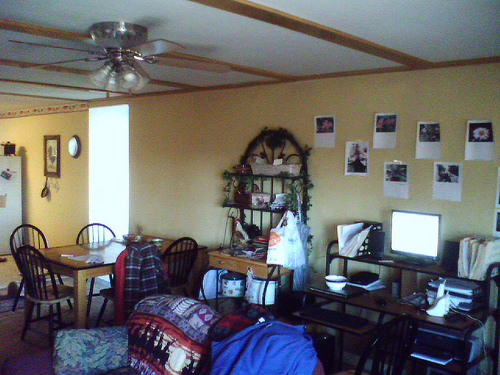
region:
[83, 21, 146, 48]
a shiny finished ceiling fan cover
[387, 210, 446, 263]
a flat screen computer monitor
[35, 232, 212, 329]
a light wood finished table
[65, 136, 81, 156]
clock with black rim hanging on wall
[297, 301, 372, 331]
a black keyboard on pull out shelf of desk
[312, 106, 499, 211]
papers hanging above computer on wall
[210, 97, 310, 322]
a stand with nonreal ivy wrapped around it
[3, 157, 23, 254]
a white refrigerator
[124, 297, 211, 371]
a knitted throw blanket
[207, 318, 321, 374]
a blue garment draped over couch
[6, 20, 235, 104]
The ceiling fan on the roof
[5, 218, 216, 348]
The table is in the room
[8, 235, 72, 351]
The chair is the color black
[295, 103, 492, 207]
The pictures on the wall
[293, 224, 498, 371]
The desk against the wall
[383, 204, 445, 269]
The monitor on the desk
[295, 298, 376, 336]
The keyboard on the desk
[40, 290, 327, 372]
The chair in the room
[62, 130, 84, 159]
The clock on the wall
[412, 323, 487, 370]
The printer on the shelf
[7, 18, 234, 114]
A ceiling fan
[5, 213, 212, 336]
A wooden dining room set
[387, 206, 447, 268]
A lit up computer monitor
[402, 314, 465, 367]
A black and grey computer printer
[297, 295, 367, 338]
A black keyboard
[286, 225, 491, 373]
A black and brown computer desk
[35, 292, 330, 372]
A sofa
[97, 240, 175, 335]
Clothes hanging on the back of a dining room chair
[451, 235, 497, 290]
Manilla file folders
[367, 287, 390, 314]
A black computer mouse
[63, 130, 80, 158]
The clock on the wall is round.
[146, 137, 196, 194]
The wall is yellow.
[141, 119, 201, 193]
The wall is smooth.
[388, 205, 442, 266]
The computer monitor is on.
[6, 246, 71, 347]
The chair is brown.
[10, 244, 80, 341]
The chair is made of wood.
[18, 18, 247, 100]
The ceiling fan is made of wood and metal.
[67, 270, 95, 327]
The table leg is brown.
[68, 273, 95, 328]
The table leg is made of wood.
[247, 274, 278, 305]
The container is white and blue.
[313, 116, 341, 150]
a picture on wall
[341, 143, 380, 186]
a picture on wall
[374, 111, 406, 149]
a picture on wall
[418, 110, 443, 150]
a picture on wall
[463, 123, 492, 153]
a picture on wall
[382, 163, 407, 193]
a picture on wall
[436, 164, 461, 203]
a picture on wall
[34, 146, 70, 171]
a picture on wall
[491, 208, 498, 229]
a picture on wall